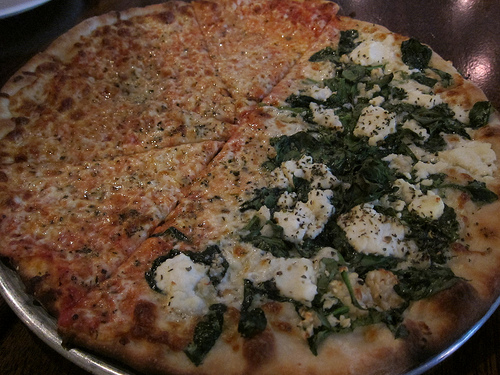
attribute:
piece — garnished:
[281, 132, 487, 299]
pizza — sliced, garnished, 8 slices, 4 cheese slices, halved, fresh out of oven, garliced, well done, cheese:
[239, 15, 280, 69]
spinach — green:
[346, 56, 359, 62]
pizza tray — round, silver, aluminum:
[9, 306, 56, 342]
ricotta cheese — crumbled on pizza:
[230, 251, 313, 298]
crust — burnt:
[67, 34, 92, 45]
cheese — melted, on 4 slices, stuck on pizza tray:
[263, 21, 276, 48]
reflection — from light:
[445, 8, 498, 95]